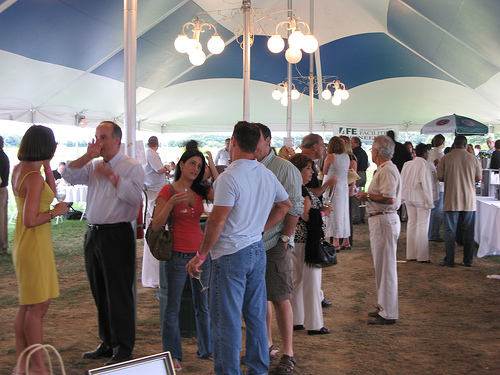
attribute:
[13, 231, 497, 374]
floors — dirty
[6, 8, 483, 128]
tent — large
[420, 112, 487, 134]
umbrella — green, white, red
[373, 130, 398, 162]
hair — gray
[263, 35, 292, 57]
light — large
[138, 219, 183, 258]
purse — brown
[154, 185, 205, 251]
shirt — red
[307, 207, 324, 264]
scarf — black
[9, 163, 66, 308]
dress — yellow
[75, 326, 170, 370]
shoes — black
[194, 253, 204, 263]
wristband — pink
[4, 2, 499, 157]
umbrella — blue, white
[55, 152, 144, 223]
shirt — white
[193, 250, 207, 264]
bracelet — pink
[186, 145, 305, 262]
shirt — red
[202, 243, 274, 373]
jeans — blue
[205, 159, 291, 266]
shirt — white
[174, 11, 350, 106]
fixtures — small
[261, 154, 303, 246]
shirt — green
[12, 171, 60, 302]
sundress — yellow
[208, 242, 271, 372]
jeans — blue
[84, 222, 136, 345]
pants — black, dress